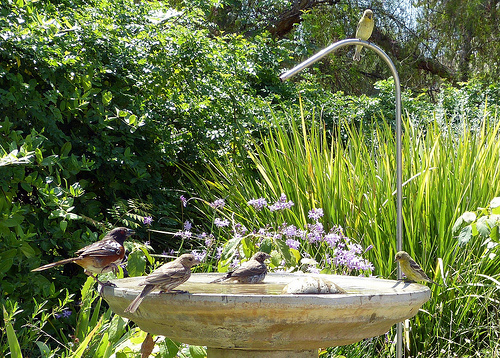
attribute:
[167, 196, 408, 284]
flowers — lavender, behind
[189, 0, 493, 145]
trees — tall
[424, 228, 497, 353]
plant — tall, green, grassy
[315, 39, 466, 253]
pipe — fountain pipe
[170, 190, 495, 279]
flowers — tall, purple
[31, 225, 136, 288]
bird — black, red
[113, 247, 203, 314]
bird — perching, red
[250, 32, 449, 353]
pipe — silver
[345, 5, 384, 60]
bird — yellow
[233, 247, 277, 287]
birds — sitting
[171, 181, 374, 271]
flowers — purple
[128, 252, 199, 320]
bird — small, yellow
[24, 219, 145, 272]
bird — brown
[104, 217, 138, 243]
head — brown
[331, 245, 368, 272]
flower — purple, peeking through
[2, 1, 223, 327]
bush — green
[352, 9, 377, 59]
bird — yellow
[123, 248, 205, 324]
bird — sitting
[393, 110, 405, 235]
pipe — metal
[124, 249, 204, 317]
bird — perching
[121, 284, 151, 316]
tail — long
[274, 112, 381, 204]
tall grass — green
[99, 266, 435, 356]
birdbath — wooden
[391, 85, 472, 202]
leaves — flat, green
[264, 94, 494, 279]
grass — behind, tall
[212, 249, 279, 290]
bird — small, brown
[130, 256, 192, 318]
bird — brown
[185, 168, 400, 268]
flowers — purple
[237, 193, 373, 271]
flowers — white